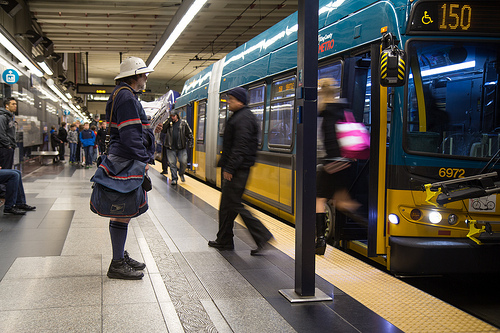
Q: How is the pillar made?
A: Of metal.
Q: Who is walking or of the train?
A: A man.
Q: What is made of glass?
A: Window.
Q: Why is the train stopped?
A: To load and unload.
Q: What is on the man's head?
A: A hat.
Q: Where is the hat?
A: On the man's head.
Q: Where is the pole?
A: On the platform.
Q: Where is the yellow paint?
A: On the platform.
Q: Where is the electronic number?
A: On the train.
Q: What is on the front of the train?
A: A headlight.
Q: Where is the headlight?
A: On the front of the train.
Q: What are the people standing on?
A: Walkway.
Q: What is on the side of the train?
A: Windows.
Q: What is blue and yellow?
A: Train.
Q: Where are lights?
A: On the ceiling.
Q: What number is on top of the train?
A: 150.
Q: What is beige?
A: Man's hat.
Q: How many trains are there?
A: One.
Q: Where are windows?
A: On a train.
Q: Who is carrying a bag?
A: Man with hat on.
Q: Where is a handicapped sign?
A: On the train.